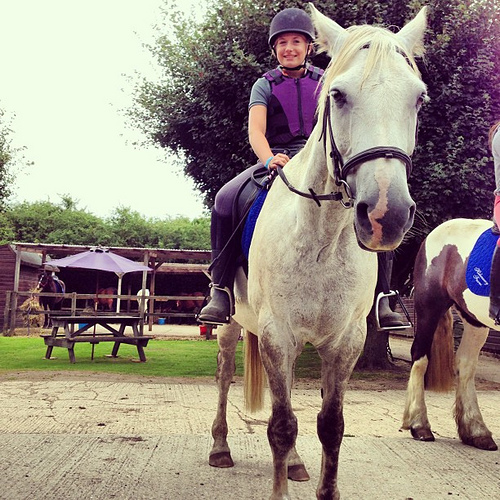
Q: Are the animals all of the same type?
A: Yes, all the animals are horses.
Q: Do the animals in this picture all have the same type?
A: Yes, all the animals are horses.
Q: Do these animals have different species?
A: No, all the animals are horses.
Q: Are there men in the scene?
A: No, there are no men.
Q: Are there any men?
A: No, there are no men.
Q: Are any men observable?
A: No, there are no men.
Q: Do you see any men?
A: No, there are no men.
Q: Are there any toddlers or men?
A: No, there are no men or toddlers.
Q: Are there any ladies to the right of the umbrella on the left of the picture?
A: Yes, there is a lady to the right of the umbrella.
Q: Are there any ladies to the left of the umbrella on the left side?
A: No, the lady is to the right of the umbrella.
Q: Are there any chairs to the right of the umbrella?
A: No, there is a lady to the right of the umbrella.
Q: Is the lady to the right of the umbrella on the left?
A: Yes, the lady is to the right of the umbrella.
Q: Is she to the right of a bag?
A: No, the lady is to the right of the umbrella.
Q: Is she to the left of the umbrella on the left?
A: No, the lady is to the right of the umbrella.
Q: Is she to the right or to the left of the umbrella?
A: The lady is to the right of the umbrella.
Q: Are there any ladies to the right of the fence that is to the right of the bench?
A: Yes, there is a lady to the right of the fence.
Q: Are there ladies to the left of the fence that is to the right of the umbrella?
A: No, the lady is to the right of the fence.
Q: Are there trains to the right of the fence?
A: No, there is a lady to the right of the fence.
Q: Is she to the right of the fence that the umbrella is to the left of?
A: Yes, the lady is to the right of the fence.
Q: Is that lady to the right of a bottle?
A: No, the lady is to the right of the fence.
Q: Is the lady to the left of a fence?
A: No, the lady is to the right of a fence.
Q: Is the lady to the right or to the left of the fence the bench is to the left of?
A: The lady is to the right of the fence.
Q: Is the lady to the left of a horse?
A: No, the lady is to the right of a horse.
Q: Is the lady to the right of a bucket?
A: Yes, the lady is to the right of a bucket.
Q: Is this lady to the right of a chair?
A: No, the lady is to the right of a bucket.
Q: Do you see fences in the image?
A: Yes, there is a fence.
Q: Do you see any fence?
A: Yes, there is a fence.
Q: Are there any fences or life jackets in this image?
A: Yes, there is a fence.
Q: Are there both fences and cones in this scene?
A: No, there is a fence but no cones.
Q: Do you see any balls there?
A: No, there are no balls.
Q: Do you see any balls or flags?
A: No, there are no balls or flags.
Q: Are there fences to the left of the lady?
A: Yes, there is a fence to the left of the lady.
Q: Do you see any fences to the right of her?
A: No, the fence is to the left of the lady.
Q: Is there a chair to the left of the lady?
A: No, there is a fence to the left of the lady.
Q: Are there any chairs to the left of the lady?
A: No, there is a fence to the left of the lady.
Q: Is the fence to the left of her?
A: Yes, the fence is to the left of a lady.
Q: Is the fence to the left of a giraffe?
A: No, the fence is to the left of a lady.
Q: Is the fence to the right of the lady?
A: No, the fence is to the left of the lady.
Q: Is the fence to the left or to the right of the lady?
A: The fence is to the left of the lady.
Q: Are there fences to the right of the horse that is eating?
A: Yes, there is a fence to the right of the horse.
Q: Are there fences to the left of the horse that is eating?
A: No, the fence is to the right of the horse.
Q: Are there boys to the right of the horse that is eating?
A: No, there is a fence to the right of the horse.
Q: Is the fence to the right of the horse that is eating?
A: Yes, the fence is to the right of the horse.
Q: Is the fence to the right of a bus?
A: No, the fence is to the right of the horse.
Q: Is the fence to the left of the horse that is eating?
A: No, the fence is to the right of the horse.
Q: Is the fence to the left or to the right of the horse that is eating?
A: The fence is to the right of the horse.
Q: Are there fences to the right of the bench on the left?
A: Yes, there is a fence to the right of the bench.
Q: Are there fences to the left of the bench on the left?
A: No, the fence is to the right of the bench.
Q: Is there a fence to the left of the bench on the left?
A: No, the fence is to the right of the bench.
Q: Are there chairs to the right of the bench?
A: No, there is a fence to the right of the bench.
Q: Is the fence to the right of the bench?
A: Yes, the fence is to the right of the bench.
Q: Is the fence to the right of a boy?
A: No, the fence is to the right of the bench.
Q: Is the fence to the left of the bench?
A: No, the fence is to the right of the bench.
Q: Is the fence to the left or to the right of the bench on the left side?
A: The fence is to the right of the bench.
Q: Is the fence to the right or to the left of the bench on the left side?
A: The fence is to the right of the bench.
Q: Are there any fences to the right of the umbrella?
A: Yes, there is a fence to the right of the umbrella.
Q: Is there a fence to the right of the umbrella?
A: Yes, there is a fence to the right of the umbrella.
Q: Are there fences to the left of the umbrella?
A: No, the fence is to the right of the umbrella.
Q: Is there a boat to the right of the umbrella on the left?
A: No, there is a fence to the right of the umbrella.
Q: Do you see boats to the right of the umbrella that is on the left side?
A: No, there is a fence to the right of the umbrella.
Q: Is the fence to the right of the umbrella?
A: Yes, the fence is to the right of the umbrella.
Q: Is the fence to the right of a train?
A: No, the fence is to the right of the umbrella.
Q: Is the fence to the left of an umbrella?
A: No, the fence is to the right of an umbrella.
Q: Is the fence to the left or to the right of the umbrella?
A: The fence is to the right of the umbrella.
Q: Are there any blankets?
A: Yes, there is a blanket.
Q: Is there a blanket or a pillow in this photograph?
A: Yes, there is a blanket.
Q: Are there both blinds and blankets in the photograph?
A: No, there is a blanket but no blinds.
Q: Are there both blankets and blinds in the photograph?
A: No, there is a blanket but no blinds.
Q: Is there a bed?
A: No, there are no beds.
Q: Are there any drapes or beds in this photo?
A: No, there are no beds or drapes.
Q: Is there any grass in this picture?
A: Yes, there is grass.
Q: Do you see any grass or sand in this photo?
A: Yes, there is grass.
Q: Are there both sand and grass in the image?
A: No, there is grass but no sand.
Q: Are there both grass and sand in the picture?
A: No, there is grass but no sand.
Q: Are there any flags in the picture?
A: No, there are no flags.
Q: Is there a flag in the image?
A: No, there are no flags.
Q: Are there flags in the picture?
A: No, there are no flags.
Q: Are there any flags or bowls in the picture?
A: No, there are no flags or bowls.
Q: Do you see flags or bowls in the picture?
A: No, there are no flags or bowls.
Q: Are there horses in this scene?
A: Yes, there is a horse.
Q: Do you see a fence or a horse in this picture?
A: Yes, there is a horse.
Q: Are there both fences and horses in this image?
A: Yes, there are both a horse and a fence.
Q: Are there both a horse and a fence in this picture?
A: Yes, there are both a horse and a fence.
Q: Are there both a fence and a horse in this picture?
A: Yes, there are both a horse and a fence.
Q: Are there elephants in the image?
A: No, there are no elephants.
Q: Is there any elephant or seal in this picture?
A: No, there are no elephants or seals.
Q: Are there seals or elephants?
A: No, there are no elephants or seals.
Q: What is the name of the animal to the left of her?
A: The animal is a horse.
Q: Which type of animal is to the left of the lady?
A: The animal is a horse.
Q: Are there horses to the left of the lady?
A: Yes, there is a horse to the left of the lady.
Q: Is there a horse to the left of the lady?
A: Yes, there is a horse to the left of the lady.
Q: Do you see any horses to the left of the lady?
A: Yes, there is a horse to the left of the lady.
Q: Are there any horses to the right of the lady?
A: No, the horse is to the left of the lady.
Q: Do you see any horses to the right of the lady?
A: No, the horse is to the left of the lady.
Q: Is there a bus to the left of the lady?
A: No, there is a horse to the left of the lady.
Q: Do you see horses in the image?
A: Yes, there is a horse.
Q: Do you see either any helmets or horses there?
A: Yes, there is a horse.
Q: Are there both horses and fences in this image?
A: Yes, there are both a horse and a fence.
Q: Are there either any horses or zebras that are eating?
A: Yes, the horse is eating.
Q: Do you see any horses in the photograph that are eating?
A: Yes, there is a horse that is eating.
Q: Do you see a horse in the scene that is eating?
A: Yes, there is a horse that is eating.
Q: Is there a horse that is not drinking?
A: Yes, there is a horse that is eating.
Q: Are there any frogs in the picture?
A: No, there are no frogs.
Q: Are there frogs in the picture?
A: No, there are no frogs.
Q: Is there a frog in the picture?
A: No, there are no frogs.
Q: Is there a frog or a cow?
A: No, there are no frogs or cows.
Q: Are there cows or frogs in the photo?
A: No, there are no frogs or cows.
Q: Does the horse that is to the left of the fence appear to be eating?
A: Yes, the horse is eating.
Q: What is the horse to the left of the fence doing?
A: The horse is eating.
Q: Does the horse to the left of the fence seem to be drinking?
A: No, the horse is eating.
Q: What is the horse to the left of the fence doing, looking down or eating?
A: The horse is eating.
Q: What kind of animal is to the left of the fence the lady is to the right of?
A: The animal is a horse.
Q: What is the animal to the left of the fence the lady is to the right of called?
A: The animal is a horse.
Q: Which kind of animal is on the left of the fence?
A: The animal is a horse.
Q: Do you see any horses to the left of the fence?
A: Yes, there is a horse to the left of the fence.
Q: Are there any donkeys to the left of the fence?
A: No, there is a horse to the left of the fence.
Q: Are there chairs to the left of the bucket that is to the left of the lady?
A: No, there is a horse to the left of the bucket.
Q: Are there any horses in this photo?
A: Yes, there is a horse.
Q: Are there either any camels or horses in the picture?
A: Yes, there is a horse.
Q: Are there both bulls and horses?
A: No, there is a horse but no bulls.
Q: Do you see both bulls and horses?
A: No, there is a horse but no bulls.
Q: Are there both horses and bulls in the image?
A: No, there is a horse but no bulls.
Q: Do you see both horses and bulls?
A: No, there is a horse but no bulls.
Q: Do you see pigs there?
A: No, there are no pigs.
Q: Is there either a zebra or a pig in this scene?
A: No, there are no pigs or zebras.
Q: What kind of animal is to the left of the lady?
A: The animal is a horse.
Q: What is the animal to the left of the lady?
A: The animal is a horse.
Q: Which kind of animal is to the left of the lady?
A: The animal is a horse.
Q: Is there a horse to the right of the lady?
A: No, the horse is to the left of the lady.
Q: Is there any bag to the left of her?
A: No, there is a horse to the left of the lady.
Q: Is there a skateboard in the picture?
A: No, there are no skateboards.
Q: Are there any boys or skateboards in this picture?
A: No, there are no skateboards or boys.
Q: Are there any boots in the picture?
A: Yes, there are boots.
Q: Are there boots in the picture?
A: Yes, there are boots.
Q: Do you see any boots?
A: Yes, there are boots.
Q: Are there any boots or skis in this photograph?
A: Yes, there are boots.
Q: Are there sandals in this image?
A: No, there are no sandals.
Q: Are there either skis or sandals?
A: No, there are no sandals or skis.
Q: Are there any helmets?
A: Yes, there is a helmet.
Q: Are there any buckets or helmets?
A: Yes, there is a helmet.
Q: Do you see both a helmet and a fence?
A: Yes, there are both a helmet and a fence.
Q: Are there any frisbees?
A: No, there are no frisbees.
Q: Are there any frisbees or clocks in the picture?
A: No, there are no frisbees or clocks.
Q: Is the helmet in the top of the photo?
A: Yes, the helmet is in the top of the image.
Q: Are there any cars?
A: No, there are no cars.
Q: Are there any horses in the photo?
A: Yes, there is a horse.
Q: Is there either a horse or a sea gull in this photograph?
A: Yes, there is a horse.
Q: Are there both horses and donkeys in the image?
A: No, there is a horse but no donkeys.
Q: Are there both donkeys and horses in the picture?
A: No, there is a horse but no donkeys.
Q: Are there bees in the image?
A: No, there are no bees.